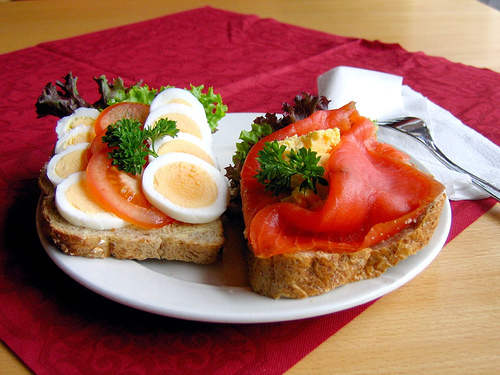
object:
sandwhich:
[35, 72, 231, 264]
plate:
[35, 111, 451, 323]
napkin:
[317, 66, 500, 202]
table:
[0, 0, 499, 374]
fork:
[372, 115, 499, 203]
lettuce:
[36, 72, 228, 133]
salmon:
[240, 100, 445, 258]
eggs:
[270, 127, 340, 167]